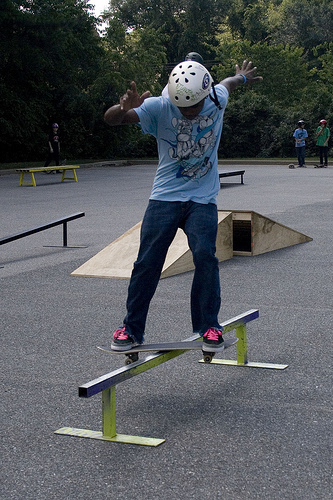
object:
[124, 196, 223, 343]
blue jeans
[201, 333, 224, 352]
tennis shoe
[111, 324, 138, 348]
tennis shoe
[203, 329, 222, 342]
strings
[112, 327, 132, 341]
strings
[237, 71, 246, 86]
wrist band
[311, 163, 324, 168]
skateboard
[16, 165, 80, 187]
skateboardjump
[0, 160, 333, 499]
road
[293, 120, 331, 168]
two people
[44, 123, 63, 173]
boy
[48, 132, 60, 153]
shirt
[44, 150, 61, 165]
pants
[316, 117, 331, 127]
helmet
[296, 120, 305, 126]
safety helmet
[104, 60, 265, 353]
boy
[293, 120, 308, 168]
boy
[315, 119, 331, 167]
boy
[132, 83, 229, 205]
shirt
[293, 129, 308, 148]
shirt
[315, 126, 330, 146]
shirt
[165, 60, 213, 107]
helmet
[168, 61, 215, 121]
head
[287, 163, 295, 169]
floor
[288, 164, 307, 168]
skateboard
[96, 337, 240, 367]
skateboard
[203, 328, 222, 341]
shoelaces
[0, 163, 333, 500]
skateboard park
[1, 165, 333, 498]
ground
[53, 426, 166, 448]
part